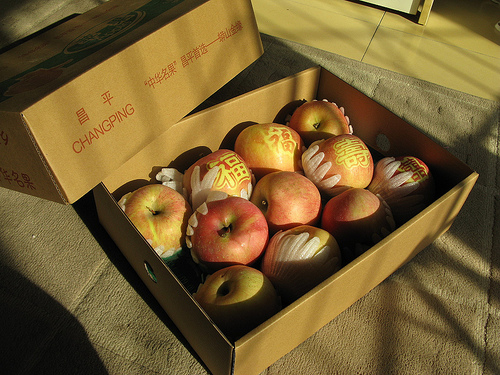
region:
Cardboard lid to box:
[0, 1, 285, 198]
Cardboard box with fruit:
[84, 65, 478, 372]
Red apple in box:
[190, 195, 265, 272]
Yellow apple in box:
[187, 255, 280, 337]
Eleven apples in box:
[113, 95, 443, 318]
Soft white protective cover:
[265, 230, 333, 290]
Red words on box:
[62, 94, 157, 151]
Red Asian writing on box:
[146, 17, 284, 92]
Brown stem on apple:
[219, 224, 233, 236]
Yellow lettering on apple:
[329, 135, 367, 175]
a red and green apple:
[123, 185, 186, 255]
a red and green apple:
[201, 265, 281, 334]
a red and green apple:
[286, 222, 339, 267]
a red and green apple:
[323, 191, 385, 245]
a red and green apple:
[283, 99, 350, 145]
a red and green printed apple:
[323, 133, 374, 193]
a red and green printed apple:
[186, 152, 250, 196]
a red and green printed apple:
[233, 123, 295, 170]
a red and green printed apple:
[390, 152, 428, 191]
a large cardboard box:
[86, 65, 479, 373]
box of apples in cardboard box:
[22, 0, 487, 367]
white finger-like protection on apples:
[135, 141, 350, 276]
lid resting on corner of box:
[1, 0, 261, 205]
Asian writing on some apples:
[200, 115, 371, 205]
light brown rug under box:
[6, 31, 488, 366]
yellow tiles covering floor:
[250, 0, 495, 105]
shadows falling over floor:
[11, 10, 478, 322]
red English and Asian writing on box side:
[65, 15, 270, 155]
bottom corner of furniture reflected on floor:
[360, 1, 440, 71]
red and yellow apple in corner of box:
[101, 171, 186, 256]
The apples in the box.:
[115, 76, 427, 316]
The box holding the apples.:
[77, 64, 483, 372]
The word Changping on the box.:
[51, 93, 148, 163]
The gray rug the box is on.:
[11, 35, 498, 358]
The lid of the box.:
[4, 13, 279, 226]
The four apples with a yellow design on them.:
[195, 119, 435, 221]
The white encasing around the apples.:
[151, 100, 379, 296]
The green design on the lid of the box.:
[37, 3, 152, 55]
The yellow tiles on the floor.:
[284, 3, 496, 96]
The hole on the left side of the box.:
[136, 260, 157, 283]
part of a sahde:
[376, 309, 398, 344]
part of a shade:
[369, 298, 431, 355]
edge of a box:
[256, 319, 273, 333]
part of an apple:
[223, 288, 264, 332]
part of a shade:
[433, 287, 467, 318]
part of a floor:
[392, 269, 423, 314]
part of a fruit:
[281, 158, 298, 213]